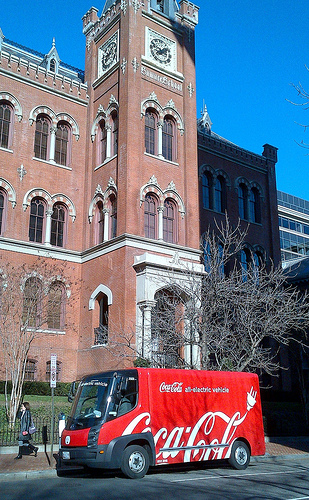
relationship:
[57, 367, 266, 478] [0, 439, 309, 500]
bus on road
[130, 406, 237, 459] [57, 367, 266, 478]
lettering on bus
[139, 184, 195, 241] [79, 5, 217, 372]
windows on building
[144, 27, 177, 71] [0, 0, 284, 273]
clock on building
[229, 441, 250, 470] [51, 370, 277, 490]
truckwheel on bus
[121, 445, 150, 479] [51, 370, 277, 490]
truckwheel on bus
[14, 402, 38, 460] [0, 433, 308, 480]
person walking on sidewalk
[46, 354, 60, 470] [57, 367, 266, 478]
pole next to bus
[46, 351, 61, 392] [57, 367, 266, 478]
sign next to bus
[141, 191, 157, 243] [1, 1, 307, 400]
window on building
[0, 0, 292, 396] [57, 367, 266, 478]
buildings behind bus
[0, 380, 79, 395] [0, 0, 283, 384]
hedge bushes in front of building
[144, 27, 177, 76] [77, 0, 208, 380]
clock on tower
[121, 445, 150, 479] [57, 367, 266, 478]
truckwheel on bus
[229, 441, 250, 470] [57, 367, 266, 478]
truckwheel on bus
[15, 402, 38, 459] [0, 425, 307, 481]
person on sidewalk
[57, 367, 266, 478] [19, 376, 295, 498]
bus on road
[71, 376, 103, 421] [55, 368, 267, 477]
front window on vehicle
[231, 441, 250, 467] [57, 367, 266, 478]
truckwheel of bus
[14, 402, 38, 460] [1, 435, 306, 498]
person walking down street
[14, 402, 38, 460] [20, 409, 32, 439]
person with jacket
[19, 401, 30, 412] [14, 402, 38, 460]
head of person